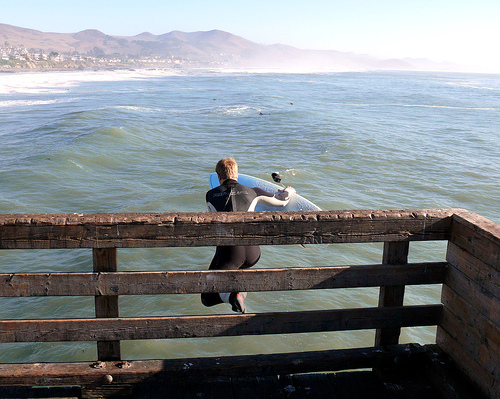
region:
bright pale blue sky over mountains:
[4, 0, 499, 70]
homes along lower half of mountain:
[1, 25, 239, 75]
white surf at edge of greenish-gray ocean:
[5, 70, 496, 364]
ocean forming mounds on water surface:
[14, 90, 176, 205]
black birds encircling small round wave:
[201, 88, 300, 125]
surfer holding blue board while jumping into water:
[186, 142, 326, 315]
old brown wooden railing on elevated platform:
[0, 195, 492, 392]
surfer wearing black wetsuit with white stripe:
[190, 151, 290, 312]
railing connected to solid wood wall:
[365, 196, 495, 391]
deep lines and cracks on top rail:
[5, 206, 457, 248]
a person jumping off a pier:
[184, 153, 328, 318]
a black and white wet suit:
[202, 184, 292, 303]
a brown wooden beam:
[16, 209, 460, 242]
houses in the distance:
[4, 54, 202, 75]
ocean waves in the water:
[58, 83, 185, 177]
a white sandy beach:
[29, 66, 146, 86]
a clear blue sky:
[39, 0, 265, 30]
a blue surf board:
[204, 153, 321, 218]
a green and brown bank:
[8, 63, 97, 75]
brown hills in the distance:
[10, 28, 288, 48]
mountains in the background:
[0, 22, 416, 71]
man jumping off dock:
[199, 155, 296, 313]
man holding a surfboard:
[199, 156, 326, 316]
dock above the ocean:
[0, 208, 498, 397]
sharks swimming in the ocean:
[211, 97, 296, 117]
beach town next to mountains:
[0, 44, 246, 66]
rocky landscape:
[0, 20, 446, 67]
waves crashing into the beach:
[1, 68, 196, 95]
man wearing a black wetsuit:
[198, 156, 300, 313]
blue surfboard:
[208, 170, 322, 211]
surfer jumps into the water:
[196, 154, 326, 311]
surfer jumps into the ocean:
[197, 155, 319, 319]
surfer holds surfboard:
[200, 158, 324, 314]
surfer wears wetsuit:
[201, 157, 326, 312]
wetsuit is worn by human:
[198, 177, 290, 313]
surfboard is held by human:
[208, 172, 322, 215]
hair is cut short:
[215, 157, 241, 181]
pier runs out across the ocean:
[1, 204, 498, 397]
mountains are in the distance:
[0, 22, 456, 72]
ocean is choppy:
[0, 72, 490, 359]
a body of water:
[302, 85, 334, 120]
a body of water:
[327, 146, 357, 165]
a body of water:
[367, 150, 397, 179]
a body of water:
[440, 174, 462, 212]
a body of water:
[444, 120, 474, 152]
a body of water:
[400, 110, 425, 141]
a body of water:
[83, 182, 120, 193]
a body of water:
[111, 145, 143, 160]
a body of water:
[72, 168, 96, 174]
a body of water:
[157, 118, 183, 143]